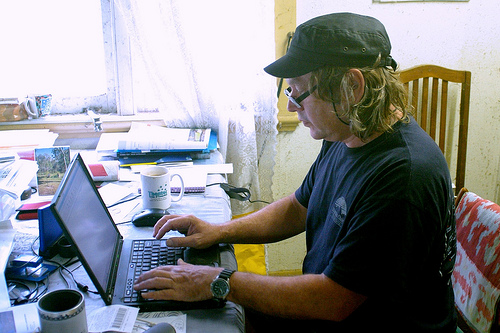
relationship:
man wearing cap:
[259, 9, 460, 331] [251, 9, 417, 100]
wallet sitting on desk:
[12, 196, 57, 223] [2, 122, 247, 331]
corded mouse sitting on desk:
[113, 207, 170, 229] [2, 122, 247, 331]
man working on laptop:
[132, 12, 458, 332] [42, 148, 227, 311]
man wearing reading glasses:
[132, 12, 458, 332] [278, 84, 323, 106]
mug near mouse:
[129, 158, 178, 208] [128, 198, 153, 224]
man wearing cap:
[132, 12, 458, 332] [263, 12, 395, 77]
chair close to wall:
[397, 65, 472, 196] [388, 5, 493, 75]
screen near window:
[115, 0, 281, 125] [112, 5, 277, 126]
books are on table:
[125, 117, 214, 157] [14, 121, 235, 315]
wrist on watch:
[205, 260, 250, 305] [209, 261, 258, 297]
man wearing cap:
[259, 9, 460, 331] [263, 12, 425, 79]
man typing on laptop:
[132, 12, 458, 332] [49, 152, 226, 313]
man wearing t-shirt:
[132, 12, 458, 332] [287, 119, 462, 331]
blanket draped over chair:
[456, 192, 498, 329] [453, 185, 499, 329]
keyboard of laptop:
[129, 240, 203, 297] [43, 148, 244, 305]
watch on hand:
[209, 267, 238, 303] [133, 258, 225, 304]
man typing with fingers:
[132, 12, 458, 332] [152, 210, 201, 251]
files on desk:
[113, 149, 212, 162] [2, 122, 247, 333]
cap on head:
[263, 12, 398, 79] [286, 12, 413, 144]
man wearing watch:
[132, 12, 458, 332] [209, 262, 238, 317]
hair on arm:
[242, 267, 326, 309] [131, 181, 445, 325]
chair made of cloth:
[452, 177, 483, 295] [455, 195, 483, 318]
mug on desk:
[139, 166, 184, 208] [2, 122, 247, 333]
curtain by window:
[134, 6, 279, 170] [0, 0, 308, 132]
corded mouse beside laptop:
[131, 208, 171, 227] [42, 148, 227, 311]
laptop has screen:
[31, 133, 281, 310] [53, 155, 127, 291]